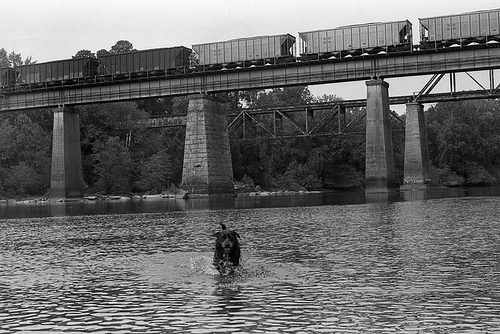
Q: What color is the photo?
A: Black and white.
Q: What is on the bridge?
A: A train.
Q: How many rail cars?
A: Five.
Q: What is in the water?
A: A dog.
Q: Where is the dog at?
A: The River.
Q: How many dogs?
A: One.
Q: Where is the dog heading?
A: Towards the camera.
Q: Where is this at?
A: Water.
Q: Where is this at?
A: In the river.